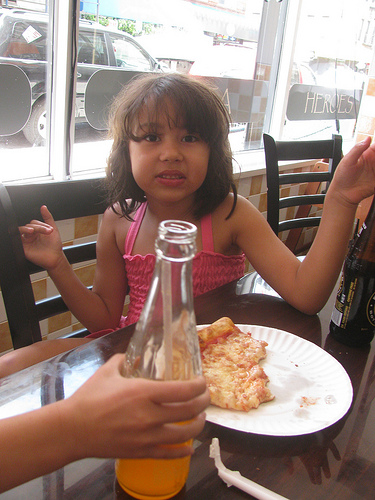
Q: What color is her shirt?
A: Pink.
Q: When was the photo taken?
A: Daytime.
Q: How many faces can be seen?
A: One.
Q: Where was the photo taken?
A: At a pizza restaurant.